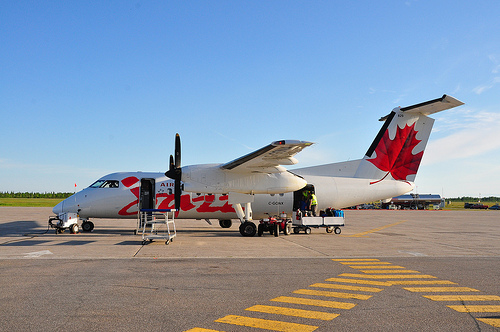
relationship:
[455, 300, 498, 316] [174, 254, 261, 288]
line painted on pavement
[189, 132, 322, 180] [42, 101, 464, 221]
wing on plane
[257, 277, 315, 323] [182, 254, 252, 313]
line on pavement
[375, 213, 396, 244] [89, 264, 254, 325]
line on pavement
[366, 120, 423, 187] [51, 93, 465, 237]
design on plane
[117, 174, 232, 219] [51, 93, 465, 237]
design on plane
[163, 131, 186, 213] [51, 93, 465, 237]
propeller on plane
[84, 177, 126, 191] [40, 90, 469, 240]
cockpit window on plane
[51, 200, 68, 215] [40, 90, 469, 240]
nose on plane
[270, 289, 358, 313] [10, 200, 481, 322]
line on pavement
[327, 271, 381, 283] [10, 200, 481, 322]
line on pavement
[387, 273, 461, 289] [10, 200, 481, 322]
line on pavement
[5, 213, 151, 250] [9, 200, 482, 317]
shadow on ground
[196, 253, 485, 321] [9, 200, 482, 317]
signs on ground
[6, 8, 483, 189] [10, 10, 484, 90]
sky in background